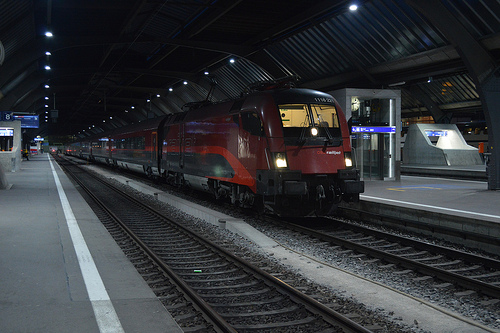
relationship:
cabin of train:
[242, 90, 355, 204] [48, 75, 361, 223]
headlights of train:
[266, 144, 357, 170] [48, 75, 361, 223]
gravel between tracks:
[227, 234, 332, 265] [61, 178, 384, 327]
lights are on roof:
[35, 28, 57, 124] [20, 5, 163, 111]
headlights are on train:
[266, 144, 357, 170] [48, 75, 361, 223]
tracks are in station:
[61, 178, 384, 327] [5, 31, 477, 313]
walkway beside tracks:
[8, 145, 94, 312] [61, 178, 384, 327]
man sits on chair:
[21, 148, 32, 157] [20, 152, 29, 168]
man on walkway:
[21, 148, 32, 157] [8, 145, 94, 312]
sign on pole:
[350, 123, 402, 138] [385, 133, 400, 180]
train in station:
[48, 75, 361, 223] [5, 31, 477, 313]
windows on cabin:
[281, 99, 343, 134] [242, 90, 355, 204]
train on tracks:
[48, 75, 361, 223] [61, 178, 384, 327]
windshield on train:
[281, 99, 343, 134] [48, 75, 361, 223]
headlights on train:
[266, 144, 357, 170] [48, 75, 361, 223]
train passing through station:
[48, 75, 361, 223] [5, 31, 477, 313]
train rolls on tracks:
[48, 75, 361, 223] [61, 178, 384, 327]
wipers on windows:
[314, 111, 340, 144] [281, 99, 343, 134]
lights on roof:
[35, 28, 57, 124] [20, 5, 163, 111]